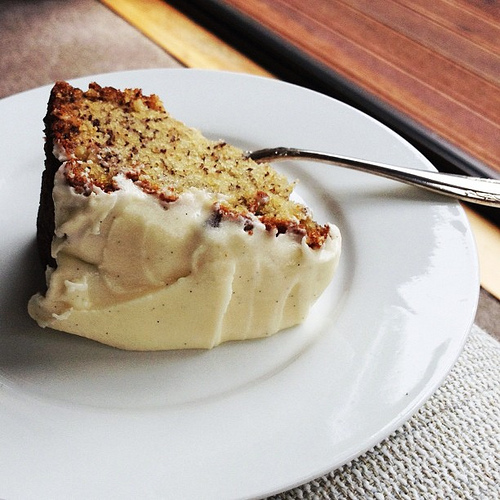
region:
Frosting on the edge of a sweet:
[59, 193, 336, 350]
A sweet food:
[16, 84, 356, 351]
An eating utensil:
[251, 127, 498, 214]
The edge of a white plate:
[0, 355, 492, 498]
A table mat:
[441, 385, 499, 499]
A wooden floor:
[321, 0, 499, 66]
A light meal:
[3, 56, 498, 495]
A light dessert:
[5, 41, 492, 496]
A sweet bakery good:
[23, 72, 355, 355]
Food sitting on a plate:
[17, 59, 499, 361]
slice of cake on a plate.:
[35, 38, 473, 388]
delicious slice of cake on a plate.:
[49, 64, 427, 401]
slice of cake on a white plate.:
[25, 65, 424, 429]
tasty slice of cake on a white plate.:
[33, 71, 397, 441]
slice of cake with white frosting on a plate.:
[10, 72, 366, 377]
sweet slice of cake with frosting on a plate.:
[35, 64, 415, 398]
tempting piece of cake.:
[35, 73, 355, 386]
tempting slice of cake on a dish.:
[31, 75, 394, 395]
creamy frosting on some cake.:
[65, 223, 342, 355]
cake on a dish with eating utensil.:
[37, 79, 401, 359]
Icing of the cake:
[46, 180, 326, 350]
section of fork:
[247, 145, 493, 207]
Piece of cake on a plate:
[27, 85, 328, 346]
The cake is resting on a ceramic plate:
[0, 65, 470, 495]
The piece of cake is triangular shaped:
[32, 85, 335, 348]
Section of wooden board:
[230, 0, 496, 170]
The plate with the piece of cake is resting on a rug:
[0, 67, 491, 495]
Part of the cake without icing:
[51, 85, 317, 235]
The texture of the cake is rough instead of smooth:
[30, 79, 331, 352]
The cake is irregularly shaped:
[24, 79, 328, 347]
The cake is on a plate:
[35, 73, 433, 415]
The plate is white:
[35, 61, 426, 358]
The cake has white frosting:
[44, 68, 384, 368]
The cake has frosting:
[51, 73, 376, 380]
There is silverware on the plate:
[249, 122, 496, 234]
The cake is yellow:
[35, 61, 372, 363]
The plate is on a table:
[24, 9, 495, 324]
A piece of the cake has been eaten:
[74, 70, 371, 265]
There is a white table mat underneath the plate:
[376, 341, 496, 482]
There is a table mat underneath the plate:
[370, 341, 487, 491]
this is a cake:
[25, 88, 312, 352]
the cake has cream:
[55, 217, 321, 343]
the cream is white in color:
[36, 192, 323, 332]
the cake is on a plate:
[4, 367, 379, 430]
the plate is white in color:
[9, 363, 304, 470]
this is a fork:
[393, 172, 464, 184]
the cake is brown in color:
[55, 101, 152, 170]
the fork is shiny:
[458, 186, 493, 200]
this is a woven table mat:
[446, 387, 493, 499]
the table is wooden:
[401, 8, 479, 114]